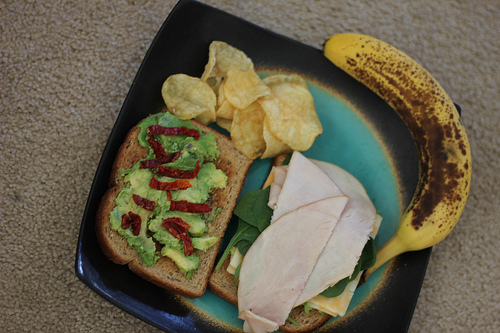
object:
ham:
[235, 149, 379, 331]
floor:
[5, 4, 482, 320]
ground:
[163, 269, 239, 298]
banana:
[322, 33, 473, 285]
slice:
[96, 109, 253, 299]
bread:
[91, 109, 253, 297]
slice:
[235, 150, 375, 330]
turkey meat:
[267, 199, 349, 299]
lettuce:
[237, 205, 264, 220]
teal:
[268, 115, 325, 152]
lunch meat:
[97, 0, 471, 332]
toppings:
[103, 109, 380, 327]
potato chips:
[162, 43, 324, 162]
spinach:
[213, 186, 273, 286]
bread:
[209, 256, 331, 332]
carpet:
[1, 0, 499, 331]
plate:
[73, 0, 459, 330]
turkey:
[210, 151, 378, 332]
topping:
[118, 126, 212, 256]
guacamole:
[109, 111, 231, 280]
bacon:
[236, 152, 382, 333]